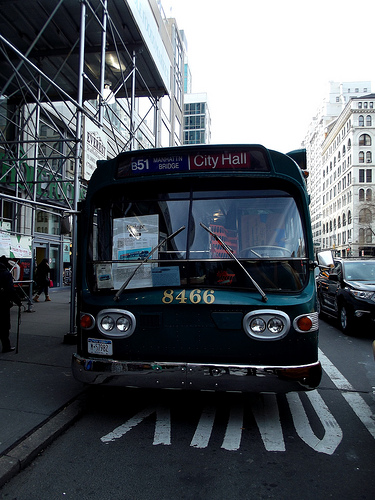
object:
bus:
[71, 145, 322, 394]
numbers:
[162, 288, 216, 304]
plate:
[87, 336, 113, 355]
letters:
[101, 387, 343, 456]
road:
[0, 391, 374, 497]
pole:
[68, 0, 81, 336]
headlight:
[268, 320, 283, 334]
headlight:
[250, 318, 267, 333]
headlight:
[117, 316, 129, 332]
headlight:
[100, 316, 114, 331]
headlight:
[296, 316, 313, 331]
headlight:
[80, 311, 95, 331]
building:
[299, 81, 375, 265]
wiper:
[198, 221, 268, 307]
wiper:
[114, 225, 188, 300]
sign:
[194, 153, 251, 169]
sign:
[131, 151, 183, 170]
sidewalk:
[0, 277, 93, 487]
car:
[314, 255, 374, 330]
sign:
[18, 258, 33, 281]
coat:
[35, 262, 50, 285]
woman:
[32, 258, 51, 304]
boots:
[44, 292, 51, 302]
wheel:
[238, 245, 293, 259]